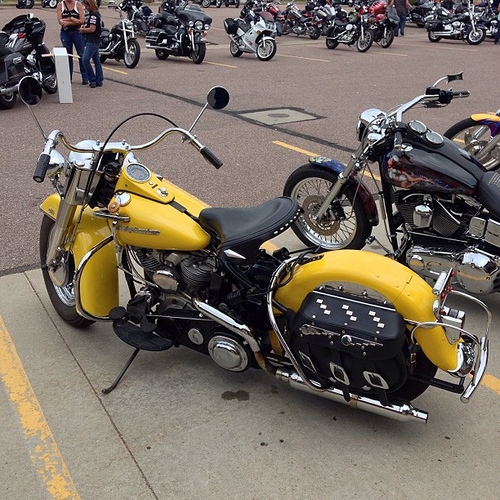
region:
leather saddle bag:
[295, 295, 410, 406]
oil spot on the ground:
[222, 387, 250, 402]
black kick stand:
[98, 350, 138, 392]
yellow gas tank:
[110, 174, 209, 250]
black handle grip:
[33, 153, 51, 183]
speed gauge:
[126, 163, 150, 181]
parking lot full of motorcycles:
[2, 1, 497, 423]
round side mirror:
[207, 86, 229, 110]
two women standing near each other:
[56, 0, 103, 87]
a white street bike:
[222, 14, 275, 59]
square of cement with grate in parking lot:
[233, 76, 324, 136]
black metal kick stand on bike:
[81, 326, 168, 426]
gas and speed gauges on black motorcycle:
[404, 103, 462, 163]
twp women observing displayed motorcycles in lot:
[47, 0, 117, 92]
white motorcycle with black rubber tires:
[217, 3, 303, 65]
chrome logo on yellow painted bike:
[104, 198, 172, 242]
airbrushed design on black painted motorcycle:
[382, 153, 468, 208]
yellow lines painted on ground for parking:
[199, 56, 368, 81]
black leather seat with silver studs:
[197, 184, 305, 259]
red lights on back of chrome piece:
[427, 264, 474, 326]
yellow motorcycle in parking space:
[3, 74, 496, 459]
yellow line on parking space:
[1, 318, 83, 498]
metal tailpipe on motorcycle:
[271, 360, 433, 429]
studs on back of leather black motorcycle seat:
[268, 195, 304, 242]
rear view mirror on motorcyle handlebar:
[184, 80, 244, 146]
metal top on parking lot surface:
[261, 103, 298, 125]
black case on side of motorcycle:
[288, 283, 414, 410]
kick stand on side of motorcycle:
[91, 334, 150, 401]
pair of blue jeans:
[77, 41, 111, 83]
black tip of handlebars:
[196, 141, 229, 176]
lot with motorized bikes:
[18, 60, 483, 401]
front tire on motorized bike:
[23, 193, 110, 308]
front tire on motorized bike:
[262, 150, 378, 246]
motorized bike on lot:
[219, 10, 286, 65]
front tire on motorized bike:
[253, 35, 279, 66]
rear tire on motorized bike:
[224, 34, 244, 59]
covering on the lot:
[252, 86, 313, 138]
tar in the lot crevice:
[290, 123, 317, 148]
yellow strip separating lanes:
[14, 413, 68, 472]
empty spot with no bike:
[293, 43, 331, 60]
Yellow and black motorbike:
[28, 88, 495, 430]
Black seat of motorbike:
[198, 198, 295, 249]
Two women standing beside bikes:
[55, 0, 108, 85]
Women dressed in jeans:
[56, 1, 106, 86]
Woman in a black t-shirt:
[78, 5, 102, 42]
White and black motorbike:
[224, 10, 281, 62]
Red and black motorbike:
[362, 0, 397, 46]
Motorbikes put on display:
[2, 0, 497, 425]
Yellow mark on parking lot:
[0, 321, 90, 493]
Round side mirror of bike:
[206, 83, 229, 114]